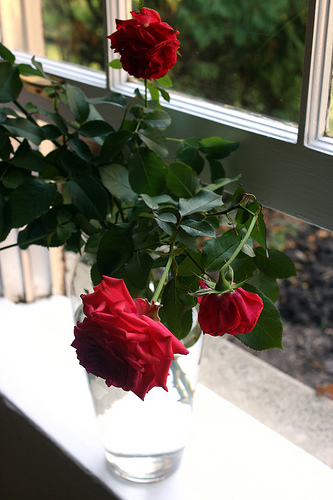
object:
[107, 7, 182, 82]
rose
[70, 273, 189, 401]
rose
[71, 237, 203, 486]
vase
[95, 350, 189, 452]
water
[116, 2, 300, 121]
window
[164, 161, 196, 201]
rose leaf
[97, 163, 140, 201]
rose leaf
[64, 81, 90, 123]
rose leaf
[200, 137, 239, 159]
rose leaf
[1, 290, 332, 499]
window sill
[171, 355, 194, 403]
rose stem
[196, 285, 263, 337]
rose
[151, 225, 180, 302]
stem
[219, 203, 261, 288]
stem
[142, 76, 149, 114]
stem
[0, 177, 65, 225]
rose leaf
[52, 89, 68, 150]
stem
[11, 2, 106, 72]
glass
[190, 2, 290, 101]
bush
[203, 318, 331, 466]
sidewalk